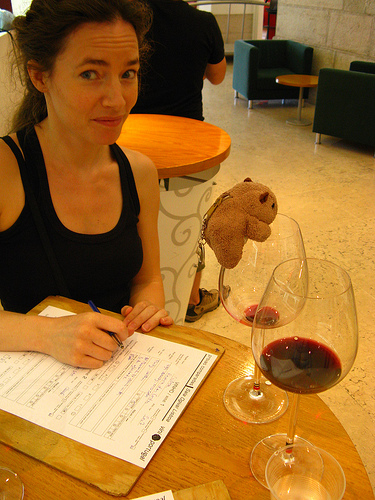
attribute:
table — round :
[144, 107, 229, 196]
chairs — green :
[232, 33, 374, 145]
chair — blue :
[236, 27, 311, 120]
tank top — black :
[0, 122, 145, 315]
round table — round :
[2, 292, 373, 499]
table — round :
[9, 296, 363, 497]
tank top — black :
[1, 126, 163, 334]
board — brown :
[13, 297, 199, 495]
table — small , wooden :
[271, 65, 318, 118]